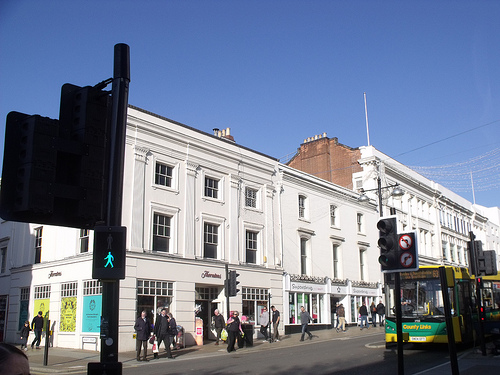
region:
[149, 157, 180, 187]
window on a building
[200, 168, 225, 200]
window on a building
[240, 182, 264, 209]
window on a building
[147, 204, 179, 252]
window on a building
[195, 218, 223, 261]
window on a building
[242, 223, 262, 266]
window on a building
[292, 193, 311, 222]
window on a building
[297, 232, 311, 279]
window on a building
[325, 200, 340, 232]
window on a building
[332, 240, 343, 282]
window on a building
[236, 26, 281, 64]
A clear blue sky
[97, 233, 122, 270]
Black street crossing light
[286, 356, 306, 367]
Small part of the black street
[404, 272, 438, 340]
Front of the bus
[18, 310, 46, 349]
A man walking with his son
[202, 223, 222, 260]
One of the windows on the building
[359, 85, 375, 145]
White pole on the roof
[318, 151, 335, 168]
Brown wall of the building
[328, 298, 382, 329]
A few pedestrians walking on the street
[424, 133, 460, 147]
Black power line in the air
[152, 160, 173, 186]
a window in the white building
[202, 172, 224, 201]
a window in the white building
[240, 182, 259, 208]
a window in the white building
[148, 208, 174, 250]
a window in the white building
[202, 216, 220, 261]
a window in the white building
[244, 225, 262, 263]
a window in the white building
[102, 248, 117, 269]
a little green "walk" man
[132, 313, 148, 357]
a person walking on the sidewalk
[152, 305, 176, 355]
a person walking on the sidewalk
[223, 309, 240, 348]
a person walking on the sidewalk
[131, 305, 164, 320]
the head of a person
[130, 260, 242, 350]
people standing on the street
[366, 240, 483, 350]
the windshield on a bus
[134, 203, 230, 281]
the windows on a building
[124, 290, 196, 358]
people standing near a building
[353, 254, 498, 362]
a green and yellow bus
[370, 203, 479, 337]
a bus near a street light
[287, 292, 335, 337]
a man wearing a jacket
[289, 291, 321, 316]
the head of a man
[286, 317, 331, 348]
the legs of a man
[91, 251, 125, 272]
green man on traffic signal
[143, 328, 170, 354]
white bag in man's hand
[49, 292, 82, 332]
yellow poster on wall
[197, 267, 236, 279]
elegant sign on top of building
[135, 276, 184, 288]
windows at top of store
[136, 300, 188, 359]
men standing on the street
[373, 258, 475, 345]
large yellow and green bus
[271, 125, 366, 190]
brown color on building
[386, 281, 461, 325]
large window in front of bus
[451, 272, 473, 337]
large door on bus